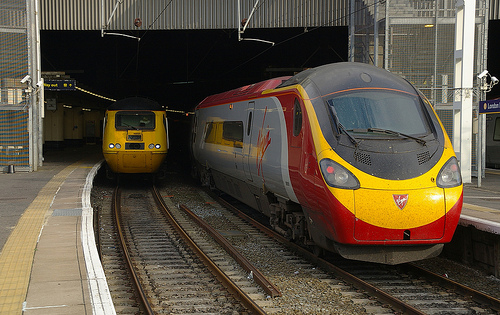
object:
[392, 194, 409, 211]
logo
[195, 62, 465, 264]
train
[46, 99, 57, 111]
sign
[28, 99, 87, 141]
wall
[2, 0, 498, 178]
train station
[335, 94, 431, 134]
window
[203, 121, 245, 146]
window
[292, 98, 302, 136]
window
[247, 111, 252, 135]
window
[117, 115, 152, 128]
window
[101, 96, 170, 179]
train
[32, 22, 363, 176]
entrance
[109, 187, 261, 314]
train tracks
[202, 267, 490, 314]
train tracks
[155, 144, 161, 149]
light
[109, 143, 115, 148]
light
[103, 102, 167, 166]
front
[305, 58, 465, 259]
front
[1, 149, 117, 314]
cement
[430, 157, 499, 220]
cement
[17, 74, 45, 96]
camera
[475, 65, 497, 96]
camera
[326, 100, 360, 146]
windshield wiper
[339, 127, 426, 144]
windshield wiper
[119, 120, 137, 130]
windshield wiper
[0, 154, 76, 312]
curbing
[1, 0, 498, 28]
sheeting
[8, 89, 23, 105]
window